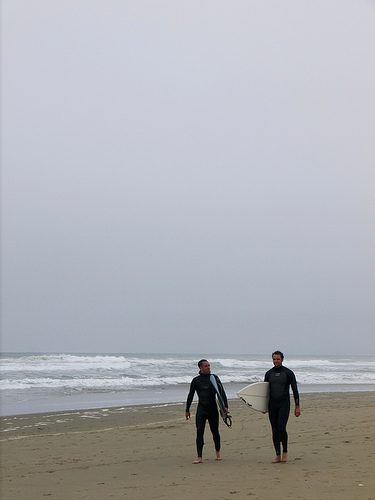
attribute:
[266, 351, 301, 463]
man — walking, looking forward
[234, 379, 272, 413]
board — white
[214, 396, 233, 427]
board — blue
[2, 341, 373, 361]
horizon — distant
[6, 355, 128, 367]
wave — white, crashing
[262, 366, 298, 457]
wetsuit — black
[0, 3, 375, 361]
sky — blue, overcast, clear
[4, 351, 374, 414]
ocean — rough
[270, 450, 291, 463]
feet — bare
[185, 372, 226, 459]
wetsuit — black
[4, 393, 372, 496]
sand — brown, sandy